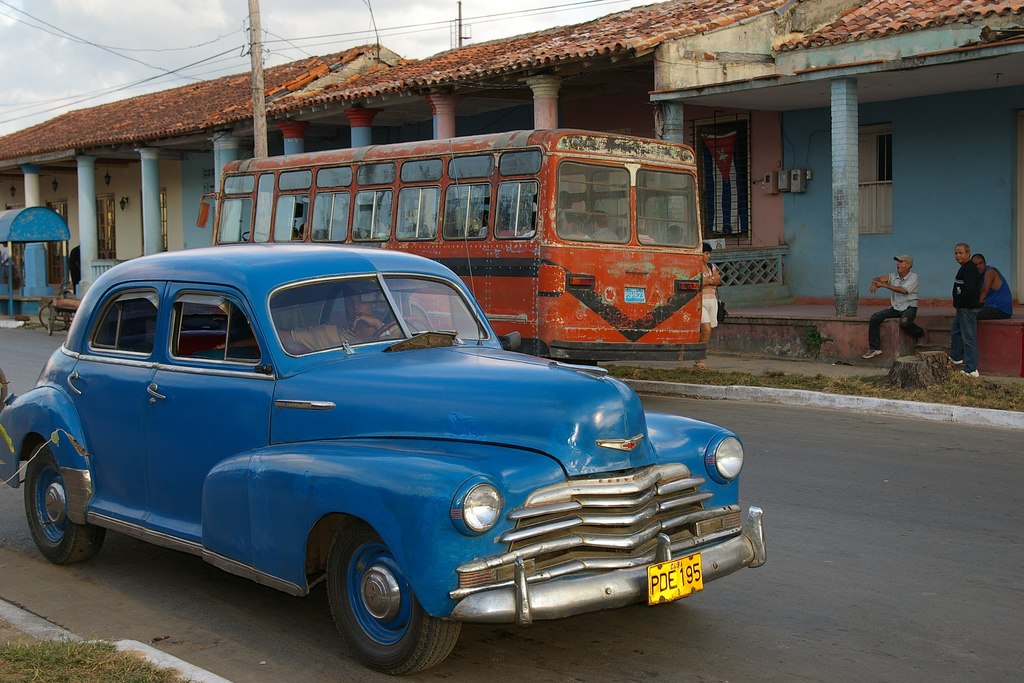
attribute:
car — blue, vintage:
[18, 241, 770, 678]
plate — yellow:
[639, 552, 719, 604]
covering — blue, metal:
[5, 206, 83, 254]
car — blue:
[16, 237, 786, 626]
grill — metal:
[470, 446, 816, 621]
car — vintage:
[33, 265, 720, 615]